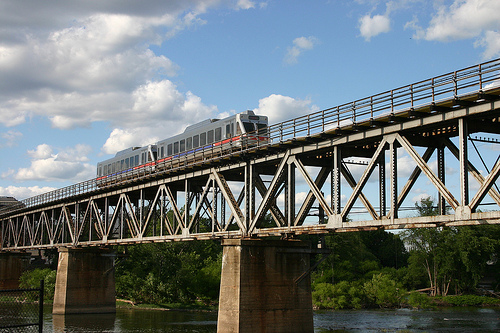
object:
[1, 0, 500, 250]
clouds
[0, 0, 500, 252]
sky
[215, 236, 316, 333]
pillar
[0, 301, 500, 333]
water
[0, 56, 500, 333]
bridge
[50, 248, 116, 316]
pillar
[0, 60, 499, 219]
rail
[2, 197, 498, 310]
forest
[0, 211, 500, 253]
bottom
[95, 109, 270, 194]
train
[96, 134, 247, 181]
stripes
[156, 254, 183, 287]
trees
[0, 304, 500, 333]
bank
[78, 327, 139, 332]
reflection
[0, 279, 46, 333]
fence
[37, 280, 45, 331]
pole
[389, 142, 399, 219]
beam